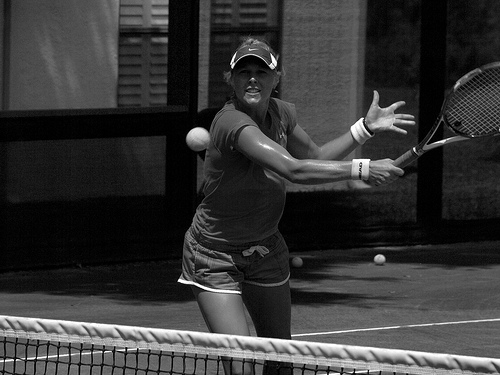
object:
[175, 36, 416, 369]
woman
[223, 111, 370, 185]
arm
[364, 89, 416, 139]
hand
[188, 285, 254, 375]
leg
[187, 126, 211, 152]
ball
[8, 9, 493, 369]
tennis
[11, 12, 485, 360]
air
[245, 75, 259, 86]
nose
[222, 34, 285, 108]
head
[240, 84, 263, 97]
mouth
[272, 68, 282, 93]
ear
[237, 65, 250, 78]
eye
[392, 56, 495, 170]
racket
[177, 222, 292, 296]
shorts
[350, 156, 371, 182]
band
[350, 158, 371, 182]
wrist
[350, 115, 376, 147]
band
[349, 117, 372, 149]
wrist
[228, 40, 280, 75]
visor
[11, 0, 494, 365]
sun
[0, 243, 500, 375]
ground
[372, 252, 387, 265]
ball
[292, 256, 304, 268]
balls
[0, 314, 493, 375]
net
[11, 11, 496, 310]
mid-air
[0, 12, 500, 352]
sports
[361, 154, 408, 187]
held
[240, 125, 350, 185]
sweat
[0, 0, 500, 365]
black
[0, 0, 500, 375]
picture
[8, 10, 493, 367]
white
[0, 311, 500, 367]
line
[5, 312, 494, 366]
white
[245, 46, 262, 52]
sign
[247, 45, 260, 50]
nike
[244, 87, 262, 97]
smile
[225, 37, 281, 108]
worn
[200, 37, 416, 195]
intensely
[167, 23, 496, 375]
played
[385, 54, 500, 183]
exist